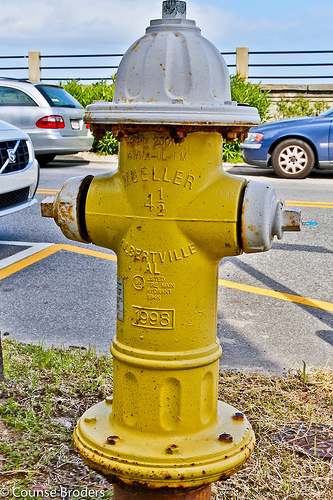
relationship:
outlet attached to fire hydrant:
[233, 168, 291, 263] [51, 42, 276, 418]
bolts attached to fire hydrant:
[94, 382, 236, 469] [51, 42, 276, 418]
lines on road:
[222, 274, 315, 317] [226, 302, 296, 328]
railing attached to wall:
[0, 48, 332, 95] [233, 30, 318, 81]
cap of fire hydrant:
[157, 1, 217, 52] [51, 42, 276, 418]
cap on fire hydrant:
[157, 1, 217, 52] [51, 42, 276, 418]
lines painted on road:
[222, 274, 315, 317] [226, 302, 296, 328]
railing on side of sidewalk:
[79, 52, 100, 62] [78, 154, 105, 164]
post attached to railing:
[234, 54, 257, 81] [79, 52, 100, 62]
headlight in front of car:
[240, 132, 281, 147] [271, 123, 331, 172]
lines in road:
[222, 274, 315, 317] [226, 302, 296, 328]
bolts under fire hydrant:
[94, 382, 236, 469] [51, 42, 276, 418]